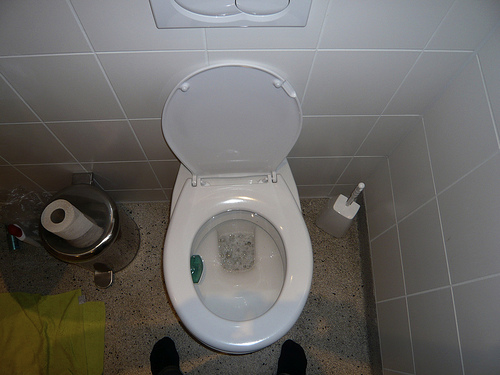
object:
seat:
[163, 168, 313, 353]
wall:
[357, 24, 498, 374]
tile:
[368, 224, 405, 302]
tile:
[395, 195, 449, 296]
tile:
[435, 152, 500, 285]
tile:
[361, 157, 396, 241]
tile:
[386, 118, 436, 223]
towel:
[0, 287, 107, 373]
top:
[6, 222, 21, 238]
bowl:
[163, 177, 315, 353]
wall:
[2, 1, 497, 201]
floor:
[0, 198, 377, 374]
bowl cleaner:
[190, 253, 204, 285]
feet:
[276, 339, 307, 374]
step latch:
[93, 269, 113, 289]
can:
[38, 172, 142, 288]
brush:
[315, 182, 365, 240]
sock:
[148, 335, 181, 374]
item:
[9, 224, 41, 249]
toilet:
[160, 62, 313, 355]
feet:
[148, 335, 183, 374]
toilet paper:
[40, 200, 92, 240]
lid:
[159, 61, 302, 178]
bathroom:
[0, 0, 500, 374]